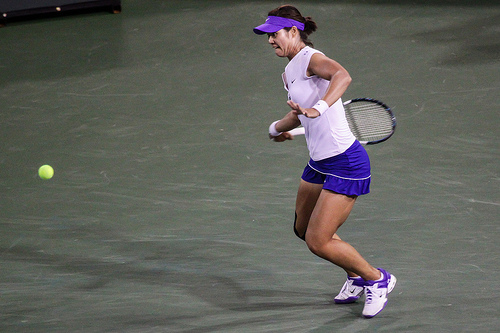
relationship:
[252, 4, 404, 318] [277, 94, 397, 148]
woman swinging racket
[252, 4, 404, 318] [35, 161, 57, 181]
woman hitting ball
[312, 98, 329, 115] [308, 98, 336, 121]
sweatband on wrist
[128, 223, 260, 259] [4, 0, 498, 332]
scuff mark on ground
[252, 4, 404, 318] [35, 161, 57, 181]
woman focusing on ball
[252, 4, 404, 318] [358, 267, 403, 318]
woman wearing shoe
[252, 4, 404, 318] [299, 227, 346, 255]
woman bending knee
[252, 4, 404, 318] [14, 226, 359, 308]
woman has shadow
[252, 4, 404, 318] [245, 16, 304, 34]
woman wearing visor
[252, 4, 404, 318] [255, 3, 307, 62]
woman has head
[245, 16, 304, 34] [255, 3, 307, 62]
visor on head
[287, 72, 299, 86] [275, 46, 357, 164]
nike logo on shirt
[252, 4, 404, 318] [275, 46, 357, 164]
woman wearing shirt